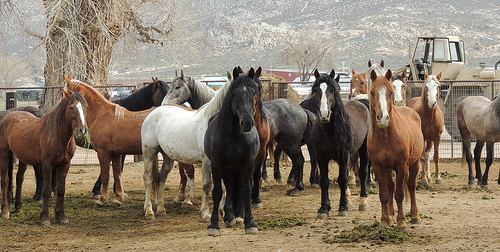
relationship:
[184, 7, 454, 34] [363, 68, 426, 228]
hill behind horse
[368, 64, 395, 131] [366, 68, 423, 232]
face on horse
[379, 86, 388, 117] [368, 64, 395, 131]
striped nose on face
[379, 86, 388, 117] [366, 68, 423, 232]
striped nose on horse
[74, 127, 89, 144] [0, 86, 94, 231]
mouth is on horse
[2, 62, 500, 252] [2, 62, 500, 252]
corral around corral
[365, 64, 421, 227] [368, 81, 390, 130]
horse with striped nose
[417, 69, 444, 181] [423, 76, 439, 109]
horse with striped nose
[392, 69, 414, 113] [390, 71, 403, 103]
horse with striped nose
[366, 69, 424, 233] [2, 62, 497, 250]
horse in a corral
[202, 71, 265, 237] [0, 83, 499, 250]
black horse in a corral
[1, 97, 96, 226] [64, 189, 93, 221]
brown horse eating hay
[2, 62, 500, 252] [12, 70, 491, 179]
corral for horses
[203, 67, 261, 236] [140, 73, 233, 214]
black horse standing in front of horse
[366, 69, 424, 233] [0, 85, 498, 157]
horse in a fence